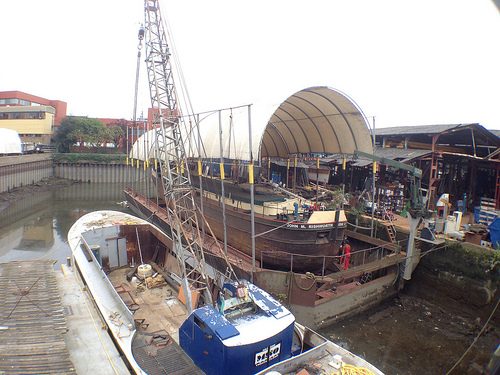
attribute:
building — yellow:
[0, 105, 54, 151]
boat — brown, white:
[124, 169, 348, 273]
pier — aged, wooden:
[1, 259, 82, 375]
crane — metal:
[131, 1, 228, 307]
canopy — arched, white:
[131, 84, 376, 167]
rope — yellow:
[335, 363, 372, 375]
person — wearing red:
[342, 238, 352, 270]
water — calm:
[0, 176, 499, 374]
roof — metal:
[366, 122, 499, 165]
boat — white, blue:
[66, 209, 384, 374]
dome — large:
[133, 82, 377, 164]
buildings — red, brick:
[0, 90, 181, 155]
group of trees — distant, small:
[50, 115, 126, 160]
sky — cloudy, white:
[3, 2, 500, 126]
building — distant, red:
[1, 89, 180, 155]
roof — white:
[128, 83, 376, 164]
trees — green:
[52, 116, 126, 154]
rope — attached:
[252, 218, 297, 241]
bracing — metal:
[125, 102, 259, 264]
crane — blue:
[134, 1, 297, 375]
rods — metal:
[121, 104, 261, 265]